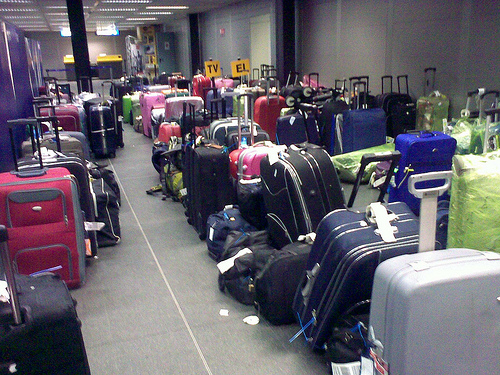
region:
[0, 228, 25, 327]
THIS IS A BAG HANDLE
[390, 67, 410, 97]
THIS IS A BAG HANDLE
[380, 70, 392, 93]
THIS IS A BAG HANDLE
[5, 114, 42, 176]
THIS IS A BAG HANDLE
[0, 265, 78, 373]
THIS IS A BAG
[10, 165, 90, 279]
THIS IS A BAG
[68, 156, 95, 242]
THIS IS A BAG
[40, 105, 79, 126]
THIS IS A BAG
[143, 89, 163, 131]
THIS IS A BAG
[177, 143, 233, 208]
THIS IS A BAG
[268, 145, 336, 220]
THIS IS A BAG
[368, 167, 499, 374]
this is a suitcase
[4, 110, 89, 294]
this is a suitcase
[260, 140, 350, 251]
this is a suitcase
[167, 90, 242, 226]
this is a suitcase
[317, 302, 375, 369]
this is a bag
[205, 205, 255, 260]
this is a bag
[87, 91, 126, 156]
this is a suitcase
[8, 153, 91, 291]
red luggage with blue trim and a handle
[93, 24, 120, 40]
white bright light on ceiling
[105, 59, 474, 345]
pile of random luggage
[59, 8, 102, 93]
support post black in color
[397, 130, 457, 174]
bright blue suit case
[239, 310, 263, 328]
white paper on floor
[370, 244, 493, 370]
grey colored luggage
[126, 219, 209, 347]
white line running down center of room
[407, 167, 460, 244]
handle to luggage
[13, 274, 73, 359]
THIS IS A BAG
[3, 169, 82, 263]
THIS IS A BAG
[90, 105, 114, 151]
THIS IS A BAG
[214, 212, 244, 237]
THIS IS A BAG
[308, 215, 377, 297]
THIS IS A BAG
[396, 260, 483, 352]
THIS IS A BAG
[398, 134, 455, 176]
THIS IS A BAG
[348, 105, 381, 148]
THIS IS A BAG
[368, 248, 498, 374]
a light grey suitcase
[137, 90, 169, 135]
a lavender color suitcase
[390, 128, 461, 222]
a medium blue suitcase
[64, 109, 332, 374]
the floor of the luggage area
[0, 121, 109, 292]
a piece of luggage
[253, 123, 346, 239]
a piece of luggage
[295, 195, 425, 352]
a piece of luggage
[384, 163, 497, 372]
a piece of luggage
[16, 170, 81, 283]
A red and gray suitcase on the floor.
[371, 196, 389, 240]
The suitcase has a white tag.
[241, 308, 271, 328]
A white tag on the ground.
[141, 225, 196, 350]
A white line in the middle of the floor.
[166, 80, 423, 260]
A lot of suitcases in the room.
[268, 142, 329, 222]
The suitcase is black.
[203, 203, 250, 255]
A blue suitcase sitting on the ground.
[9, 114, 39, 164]
Black handle on the suitcase.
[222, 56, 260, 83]
A yellow sign above the suitcases.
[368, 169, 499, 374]
suitcase is next to suitcase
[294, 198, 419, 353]
suitcase is next to suitcase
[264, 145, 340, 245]
suitcase is next to suitcase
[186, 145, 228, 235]
suitcase is next to suitcase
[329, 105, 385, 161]
suitcase is next to suitcase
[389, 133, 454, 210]
suitcase is next to suitcase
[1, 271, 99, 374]
suitcase is next to suitcase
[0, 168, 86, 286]
suitcase is next to suitcase